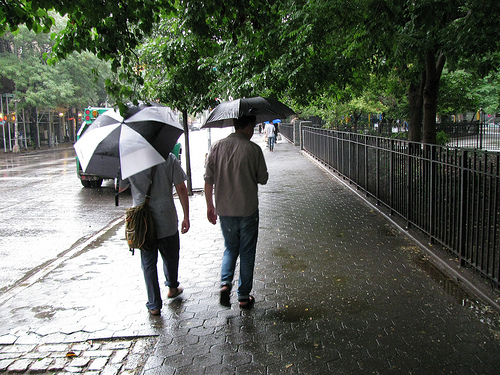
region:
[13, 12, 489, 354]
pedestrians on a rainy street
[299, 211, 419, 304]
brick pavers slick with rain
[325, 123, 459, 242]
a black iron fence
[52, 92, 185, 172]
a black and white umbrella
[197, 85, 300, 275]
a man holding a black umbrella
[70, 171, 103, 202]
spray from a moving vehicle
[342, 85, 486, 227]
a public park area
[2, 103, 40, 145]
a street light in the distance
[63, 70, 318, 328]
2 men walking down the street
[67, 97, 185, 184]
a black and white umbrella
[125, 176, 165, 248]
a brown bag slung on a person's shoulder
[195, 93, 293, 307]
a man with an umbrella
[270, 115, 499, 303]
a long black fence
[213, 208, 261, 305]
a man wearing blue jeans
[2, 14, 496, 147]
a large tree overhanging the sidewalk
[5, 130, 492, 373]
ground is made of bricks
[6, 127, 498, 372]
the ground is wet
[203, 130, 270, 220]
man wearing a gray shirt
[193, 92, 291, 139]
man holding a black and white umbrella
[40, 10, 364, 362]
two people on the sidewalk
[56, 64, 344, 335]
they both have umbrellas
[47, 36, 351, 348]
they are carrying umbrellas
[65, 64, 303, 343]
they are holding umbrellas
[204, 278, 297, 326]
he is wearing sandals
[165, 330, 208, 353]
the tiles are hexagons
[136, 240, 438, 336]
the ground has a hexagonal pattern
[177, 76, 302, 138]
a solid black umbrella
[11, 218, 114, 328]
The road is wet and slippery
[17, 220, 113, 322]
The road is wet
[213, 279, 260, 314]
A person wearing sandals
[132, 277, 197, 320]
A person wearing sandals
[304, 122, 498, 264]
A fence on the right side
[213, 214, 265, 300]
A person with blue jeans on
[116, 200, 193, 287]
A person with a backpack on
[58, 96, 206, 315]
A person holding a umbrella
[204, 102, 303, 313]
A person holding a umbrella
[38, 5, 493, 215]
A tree over the two people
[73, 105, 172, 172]
A black and white umbrella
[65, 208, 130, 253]
Pools of water by the curb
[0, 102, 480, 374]
The ground is wet with rain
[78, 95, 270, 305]
Two men walking side by side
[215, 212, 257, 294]
A pair of jeans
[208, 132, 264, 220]
A white shirt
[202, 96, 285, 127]
A gray umbrella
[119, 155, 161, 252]
A tan bag around the man's chest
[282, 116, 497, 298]
A black fence by the sidewalk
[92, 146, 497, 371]
A brick sidewalk by the road